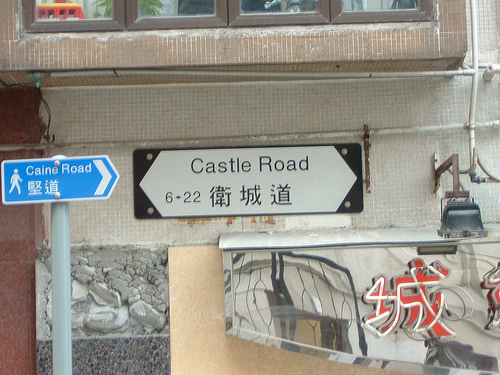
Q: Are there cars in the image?
A: No, there are no cars.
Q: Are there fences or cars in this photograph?
A: No, there are no cars or fences.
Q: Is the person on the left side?
A: Yes, the person is on the left of the image.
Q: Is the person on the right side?
A: No, the person is on the left of the image.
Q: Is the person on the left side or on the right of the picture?
A: The person is on the left of the image.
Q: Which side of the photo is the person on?
A: The person is on the left of the image.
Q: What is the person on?
A: The person is on the sign.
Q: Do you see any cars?
A: No, there are no cars.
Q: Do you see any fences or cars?
A: No, there are no cars or fences.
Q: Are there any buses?
A: No, there are no buses.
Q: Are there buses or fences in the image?
A: No, there are no buses or fences.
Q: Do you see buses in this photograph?
A: No, there are no buses.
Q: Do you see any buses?
A: No, there are no buses.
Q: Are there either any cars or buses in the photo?
A: No, there are no buses or cars.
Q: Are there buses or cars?
A: No, there are no buses or cars.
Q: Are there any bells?
A: No, there are no bells.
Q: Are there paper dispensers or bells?
A: No, there are no bells or paper dispensers.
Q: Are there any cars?
A: No, there are no cars.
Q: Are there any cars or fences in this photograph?
A: No, there are no cars or fences.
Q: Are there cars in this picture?
A: No, there are no cars.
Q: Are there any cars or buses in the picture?
A: No, there are no cars or buses.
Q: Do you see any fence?
A: No, there are no fences.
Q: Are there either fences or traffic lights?
A: No, there are no fences or traffic lights.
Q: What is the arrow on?
A: The arrow is on the sign.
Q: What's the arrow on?
A: The arrow is on the sign.